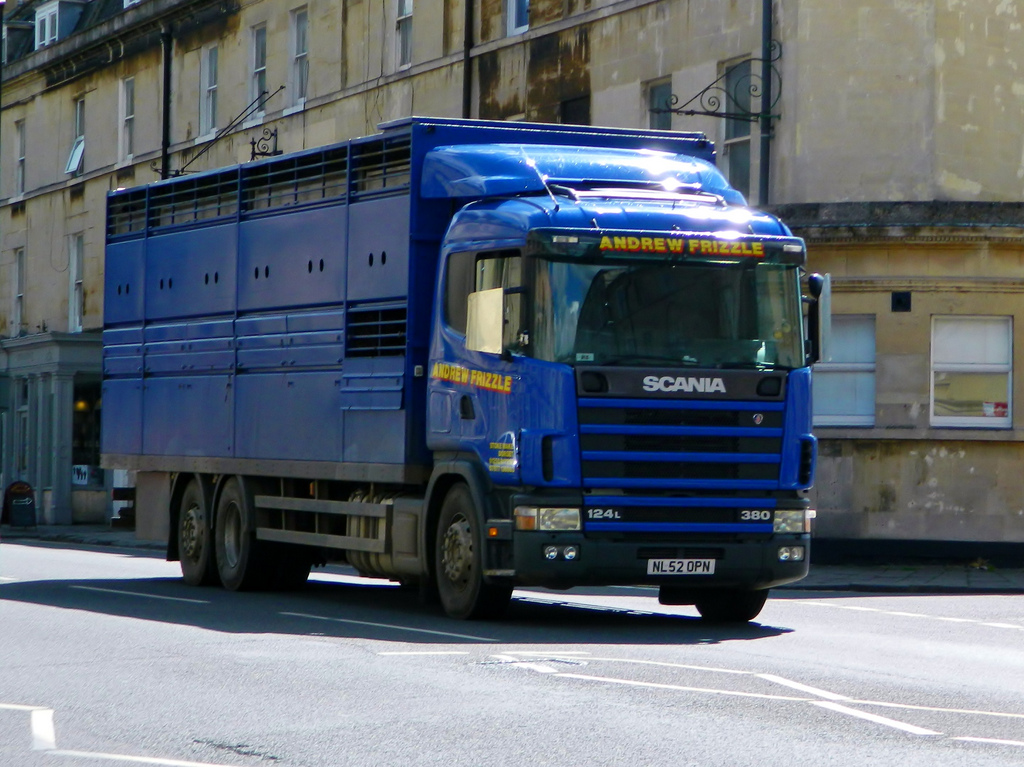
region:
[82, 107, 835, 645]
the truck is blue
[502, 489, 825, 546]
front lights of a truck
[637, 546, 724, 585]
the licence plate is white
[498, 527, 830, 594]
four lights on a bumper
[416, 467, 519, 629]
front wheel of a truck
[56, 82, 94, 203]
the window is open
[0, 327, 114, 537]
front door of a building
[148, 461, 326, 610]
back wheels of a truck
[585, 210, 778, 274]
yellow letters on a truck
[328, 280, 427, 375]
the vent of a truck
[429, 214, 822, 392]
the front window of a truck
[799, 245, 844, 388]
window on the right side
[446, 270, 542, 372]
window on the left side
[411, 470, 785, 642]
front wheels of a truck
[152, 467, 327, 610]
back wheel of a truck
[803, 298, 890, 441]
the window is white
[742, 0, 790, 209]
a pipe on the wall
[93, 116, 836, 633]
large blue truck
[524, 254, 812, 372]
windshield on blue truck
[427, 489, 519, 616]
tire on blue truck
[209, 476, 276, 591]
tire on blue truck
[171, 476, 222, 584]
tire on blue truck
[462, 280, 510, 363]
mirror on truck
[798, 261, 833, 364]
mirror on truck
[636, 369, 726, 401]
name of truck on front of truck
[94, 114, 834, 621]
a large blue truck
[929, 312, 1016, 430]
a white window on a building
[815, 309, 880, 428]
a white window on a building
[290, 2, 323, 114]
a white window on a building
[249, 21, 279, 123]
a white window on a building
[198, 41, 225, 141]
a white window on a building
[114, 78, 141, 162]
a white window on a building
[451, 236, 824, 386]
front window on a truck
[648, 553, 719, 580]
license plate on a truck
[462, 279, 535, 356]
side mirror on a truck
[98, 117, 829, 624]
the truck is large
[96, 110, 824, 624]
the truck is blue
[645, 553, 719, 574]
the license plate is white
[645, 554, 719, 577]
the black letters on the license plate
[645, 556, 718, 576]
the black numbers on the license plate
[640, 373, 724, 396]
the letters are white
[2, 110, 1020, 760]
the blue truck on the road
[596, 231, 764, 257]
the words ANDREW FRIZZLE is yellow and red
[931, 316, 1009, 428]
glass window on building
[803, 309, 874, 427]
glass window on building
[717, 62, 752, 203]
glass window on building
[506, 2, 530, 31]
glass window on building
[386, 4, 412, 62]
glass window on building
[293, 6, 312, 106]
glass window on building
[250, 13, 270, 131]
glass window on building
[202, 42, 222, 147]
glass window on building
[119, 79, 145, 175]
glass window on building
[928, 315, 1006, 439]
A window on a building.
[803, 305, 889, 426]
A window on a building.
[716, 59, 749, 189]
A window on a building.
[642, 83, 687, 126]
A window on a building.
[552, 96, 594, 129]
A window on a building.